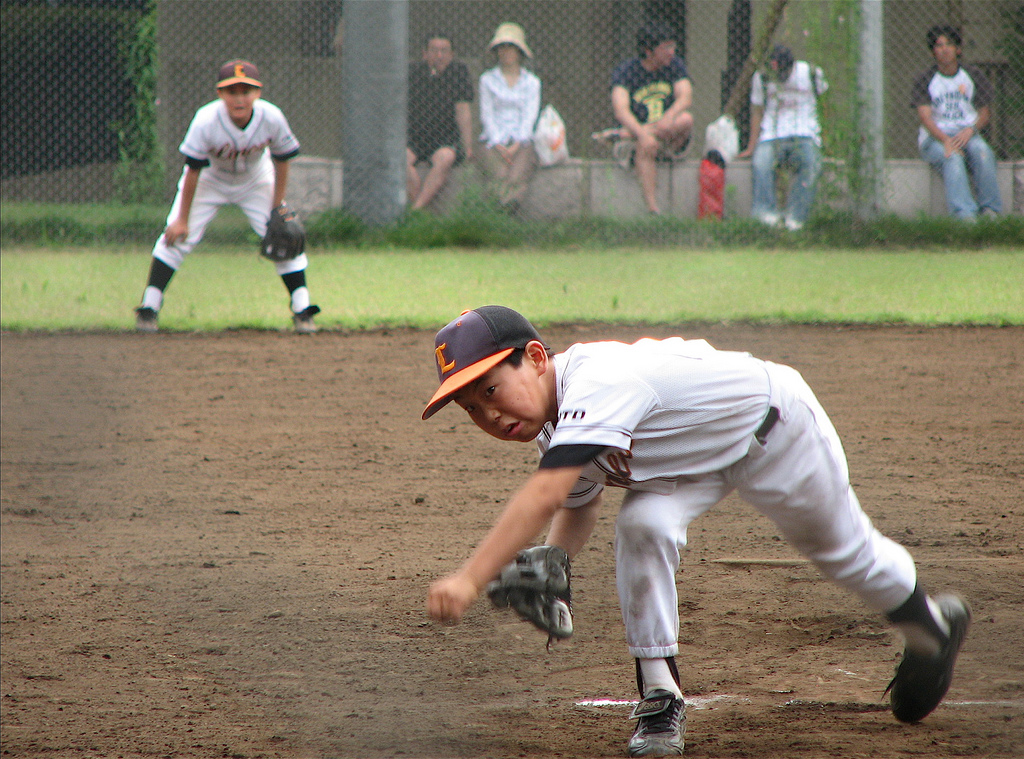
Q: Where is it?
A: This is at the field.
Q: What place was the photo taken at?
A: It was taken at the field.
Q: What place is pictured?
A: It is a field.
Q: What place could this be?
A: It is a field.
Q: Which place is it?
A: It is a field.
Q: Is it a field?
A: Yes, it is a field.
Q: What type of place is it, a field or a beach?
A: It is a field.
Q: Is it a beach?
A: No, it is a field.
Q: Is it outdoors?
A: Yes, it is outdoors.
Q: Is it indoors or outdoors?
A: It is outdoors.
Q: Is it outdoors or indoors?
A: It is outdoors.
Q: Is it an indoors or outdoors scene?
A: It is outdoors.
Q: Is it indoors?
A: No, it is outdoors.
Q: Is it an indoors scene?
A: No, it is outdoors.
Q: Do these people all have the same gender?
A: No, they are both male and female.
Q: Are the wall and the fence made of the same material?
A: No, the wall is made of concrete and the fence is made of metal.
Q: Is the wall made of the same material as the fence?
A: No, the wall is made of concrete and the fence is made of metal.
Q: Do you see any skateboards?
A: No, there are no skateboards.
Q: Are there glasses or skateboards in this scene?
A: No, there are no skateboards or glasses.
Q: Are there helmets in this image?
A: No, there are no helmets.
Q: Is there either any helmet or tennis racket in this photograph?
A: No, there are no helmets or rackets.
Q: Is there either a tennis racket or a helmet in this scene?
A: No, there are no helmets or rackets.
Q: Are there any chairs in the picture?
A: No, there are no chairs.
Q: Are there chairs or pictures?
A: No, there are no chairs or pictures.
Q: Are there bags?
A: Yes, there is a bag.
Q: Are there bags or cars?
A: Yes, there is a bag.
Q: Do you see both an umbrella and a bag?
A: No, there is a bag but no umbrellas.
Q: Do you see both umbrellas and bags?
A: No, there is a bag but no umbrellas.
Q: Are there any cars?
A: No, there are no cars.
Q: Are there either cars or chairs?
A: No, there are no cars or chairs.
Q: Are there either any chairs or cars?
A: No, there are no cars or chairs.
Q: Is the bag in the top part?
A: Yes, the bag is in the top of the image.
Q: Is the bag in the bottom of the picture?
A: No, the bag is in the top of the image.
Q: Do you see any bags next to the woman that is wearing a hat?
A: Yes, there is a bag next to the woman.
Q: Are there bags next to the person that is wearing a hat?
A: Yes, there is a bag next to the woman.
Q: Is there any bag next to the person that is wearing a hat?
A: Yes, there is a bag next to the woman.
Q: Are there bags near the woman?
A: Yes, there is a bag near the woman.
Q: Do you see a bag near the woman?
A: Yes, there is a bag near the woman.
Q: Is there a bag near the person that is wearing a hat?
A: Yes, there is a bag near the woman.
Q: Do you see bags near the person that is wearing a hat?
A: Yes, there is a bag near the woman.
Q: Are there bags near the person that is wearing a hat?
A: Yes, there is a bag near the woman.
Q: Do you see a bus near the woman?
A: No, there is a bag near the woman.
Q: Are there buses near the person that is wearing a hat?
A: No, there is a bag near the woman.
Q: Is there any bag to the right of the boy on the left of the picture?
A: Yes, there is a bag to the right of the boy.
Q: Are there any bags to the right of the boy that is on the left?
A: Yes, there is a bag to the right of the boy.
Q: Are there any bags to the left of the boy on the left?
A: No, the bag is to the right of the boy.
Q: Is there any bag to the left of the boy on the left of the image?
A: No, the bag is to the right of the boy.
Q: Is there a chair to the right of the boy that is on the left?
A: No, there is a bag to the right of the boy.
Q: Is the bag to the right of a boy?
A: Yes, the bag is to the right of a boy.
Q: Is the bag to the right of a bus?
A: No, the bag is to the right of a boy.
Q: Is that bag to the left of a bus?
A: No, the bag is to the left of a man.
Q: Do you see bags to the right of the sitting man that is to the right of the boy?
A: Yes, there is a bag to the right of the man.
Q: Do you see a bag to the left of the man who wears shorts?
A: No, the bag is to the right of the man.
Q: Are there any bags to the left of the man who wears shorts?
A: No, the bag is to the right of the man.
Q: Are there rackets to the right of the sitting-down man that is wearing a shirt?
A: No, there is a bag to the right of the man.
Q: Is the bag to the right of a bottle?
A: No, the bag is to the right of a man.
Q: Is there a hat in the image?
A: Yes, there is a hat.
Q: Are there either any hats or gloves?
A: Yes, there is a hat.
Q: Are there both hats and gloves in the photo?
A: Yes, there are both a hat and gloves.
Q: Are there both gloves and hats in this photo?
A: Yes, there are both a hat and gloves.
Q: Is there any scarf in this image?
A: No, there are no scarves.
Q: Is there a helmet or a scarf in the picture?
A: No, there are no scarves or helmets.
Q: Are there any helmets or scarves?
A: No, there are no scarves or helmets.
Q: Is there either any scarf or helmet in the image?
A: No, there are no scarves or helmets.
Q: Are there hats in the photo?
A: Yes, there is a hat.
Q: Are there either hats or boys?
A: Yes, there is a hat.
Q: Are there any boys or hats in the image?
A: Yes, there is a hat.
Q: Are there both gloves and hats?
A: Yes, there are both a hat and gloves.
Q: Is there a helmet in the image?
A: No, there are no helmets.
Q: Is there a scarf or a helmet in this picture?
A: No, there are no helmets or scarves.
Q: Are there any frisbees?
A: No, there are no frisbees.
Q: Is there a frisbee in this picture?
A: No, there are no frisbees.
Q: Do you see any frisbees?
A: No, there are no frisbees.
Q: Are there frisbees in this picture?
A: No, there are no frisbees.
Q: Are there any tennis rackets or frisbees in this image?
A: No, there are no frisbees or tennis rackets.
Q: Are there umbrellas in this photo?
A: No, there are no umbrellas.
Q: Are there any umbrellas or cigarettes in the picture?
A: No, there are no umbrellas or cigarettes.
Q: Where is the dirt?
A: The dirt is on the field.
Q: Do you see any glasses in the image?
A: No, there are no glasses.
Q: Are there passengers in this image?
A: No, there are no passengers.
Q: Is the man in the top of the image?
A: Yes, the man is in the top of the image.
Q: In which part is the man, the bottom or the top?
A: The man is in the top of the image.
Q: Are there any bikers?
A: No, there are no bikers.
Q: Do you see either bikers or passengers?
A: No, there are no bikers or passengers.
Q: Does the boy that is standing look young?
A: Yes, the boy is young.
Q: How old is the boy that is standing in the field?
A: The boy is young.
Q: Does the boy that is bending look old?
A: No, the boy is young.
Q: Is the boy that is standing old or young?
A: The boy is young.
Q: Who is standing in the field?
A: The boy is standing in the field.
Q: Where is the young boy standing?
A: The boy is standing in the field.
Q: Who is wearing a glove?
A: The boy is wearing a glove.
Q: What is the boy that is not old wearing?
A: The boy is wearing a glove.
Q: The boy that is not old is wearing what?
A: The boy is wearing a glove.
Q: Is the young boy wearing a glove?
A: Yes, the boy is wearing a glove.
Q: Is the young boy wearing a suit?
A: No, the boy is wearing a glove.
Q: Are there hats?
A: Yes, there is a hat.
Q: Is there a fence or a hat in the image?
A: Yes, there is a hat.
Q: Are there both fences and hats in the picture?
A: Yes, there are both a hat and a fence.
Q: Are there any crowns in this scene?
A: No, there are no crowns.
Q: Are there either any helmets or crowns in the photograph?
A: No, there are no crowns or helmets.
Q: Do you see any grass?
A: Yes, there is grass.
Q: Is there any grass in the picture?
A: Yes, there is grass.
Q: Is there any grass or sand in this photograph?
A: Yes, there is grass.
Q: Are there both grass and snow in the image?
A: No, there is grass but no snow.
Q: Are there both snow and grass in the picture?
A: No, there is grass but no snow.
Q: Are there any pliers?
A: No, there are no pliers.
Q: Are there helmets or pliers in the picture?
A: No, there are no pliers or helmets.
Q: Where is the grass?
A: The grass is on the field.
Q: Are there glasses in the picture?
A: No, there are no glasses.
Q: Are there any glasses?
A: No, there are no glasses.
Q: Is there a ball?
A: No, there are no balls.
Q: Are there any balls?
A: No, there are no balls.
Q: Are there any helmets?
A: No, there are no helmets.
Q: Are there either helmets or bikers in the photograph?
A: No, there are no helmets or bikers.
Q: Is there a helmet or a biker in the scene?
A: No, there are no helmets or bikers.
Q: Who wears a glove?
A: The boy wears a glove.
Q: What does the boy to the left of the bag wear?
A: The boy wears a glove.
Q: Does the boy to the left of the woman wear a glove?
A: Yes, the boy wears a glove.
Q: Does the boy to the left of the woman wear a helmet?
A: No, the boy wears a glove.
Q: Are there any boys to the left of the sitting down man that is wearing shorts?
A: Yes, there is a boy to the left of the man.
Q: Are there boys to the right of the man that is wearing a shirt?
A: No, the boy is to the left of the man.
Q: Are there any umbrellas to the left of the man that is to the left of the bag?
A: No, there is a boy to the left of the man.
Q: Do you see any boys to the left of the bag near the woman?
A: Yes, there is a boy to the left of the bag.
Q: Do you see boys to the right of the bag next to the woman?
A: No, the boy is to the left of the bag.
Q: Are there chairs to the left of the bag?
A: No, there is a boy to the left of the bag.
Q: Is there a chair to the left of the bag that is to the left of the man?
A: No, there is a boy to the left of the bag.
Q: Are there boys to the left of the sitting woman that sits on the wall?
A: Yes, there is a boy to the left of the woman.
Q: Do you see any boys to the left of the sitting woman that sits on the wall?
A: Yes, there is a boy to the left of the woman.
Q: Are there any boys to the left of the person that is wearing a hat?
A: Yes, there is a boy to the left of the woman.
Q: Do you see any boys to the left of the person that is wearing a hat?
A: Yes, there is a boy to the left of the woman.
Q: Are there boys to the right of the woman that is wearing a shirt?
A: No, the boy is to the left of the woman.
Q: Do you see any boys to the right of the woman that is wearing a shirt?
A: No, the boy is to the left of the woman.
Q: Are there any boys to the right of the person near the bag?
A: No, the boy is to the left of the woman.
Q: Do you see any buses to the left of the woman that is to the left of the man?
A: No, there is a boy to the left of the woman.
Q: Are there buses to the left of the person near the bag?
A: No, there is a boy to the left of the woman.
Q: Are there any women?
A: Yes, there is a woman.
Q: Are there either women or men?
A: Yes, there is a woman.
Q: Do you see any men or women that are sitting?
A: Yes, the woman is sitting.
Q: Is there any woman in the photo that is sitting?
A: Yes, there is a woman that is sitting.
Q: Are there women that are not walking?
A: Yes, there is a woman that is sitting.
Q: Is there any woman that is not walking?
A: Yes, there is a woman that is sitting.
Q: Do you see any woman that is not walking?
A: Yes, there is a woman that is sitting .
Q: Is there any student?
A: No, there are no students.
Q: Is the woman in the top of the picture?
A: Yes, the woman is in the top of the image.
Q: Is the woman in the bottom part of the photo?
A: No, the woman is in the top of the image.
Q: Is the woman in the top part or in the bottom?
A: The woman is in the top of the image.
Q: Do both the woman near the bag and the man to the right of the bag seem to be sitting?
A: Yes, both the woman and the man are sitting.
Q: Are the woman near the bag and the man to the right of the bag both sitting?
A: Yes, both the woman and the man are sitting.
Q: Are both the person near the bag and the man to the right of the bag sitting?
A: Yes, both the woman and the man are sitting.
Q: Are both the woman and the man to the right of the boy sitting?
A: Yes, both the woman and the man are sitting.